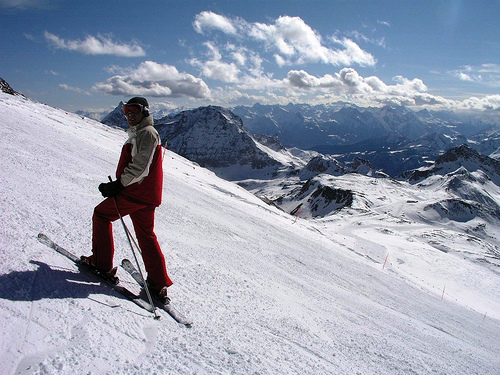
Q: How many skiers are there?
A: One.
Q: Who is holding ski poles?
A: A man.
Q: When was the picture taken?
A: Daytime.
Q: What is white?
A: Snow.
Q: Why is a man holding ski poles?
A: To ski.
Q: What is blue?
A: Sky.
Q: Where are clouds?
A: In the sky.